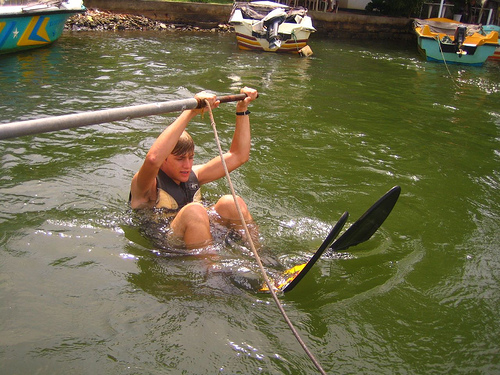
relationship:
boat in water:
[2, 2, 88, 55] [5, 30, 498, 374]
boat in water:
[411, 14, 499, 62] [5, 30, 498, 374]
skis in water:
[231, 184, 403, 295] [5, 30, 498, 374]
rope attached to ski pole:
[204, 99, 326, 374] [0, 94, 262, 139]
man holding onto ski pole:
[128, 86, 262, 273] [0, 94, 262, 139]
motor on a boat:
[455, 25, 467, 56] [411, 14, 499, 62]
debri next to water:
[65, 7, 234, 33] [5, 30, 498, 374]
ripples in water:
[2, 39, 498, 372] [5, 30, 498, 374]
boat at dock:
[411, 14, 499, 62] [85, 0, 499, 47]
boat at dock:
[226, 0, 318, 59] [85, 0, 499, 47]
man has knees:
[128, 86, 262, 273] [184, 192, 243, 221]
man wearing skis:
[128, 86, 262, 273] [231, 184, 403, 295]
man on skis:
[128, 86, 262, 273] [231, 184, 403, 295]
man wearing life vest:
[128, 86, 262, 273] [128, 170, 202, 229]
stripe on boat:
[427, 56, 483, 67] [411, 14, 499, 62]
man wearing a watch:
[128, 86, 262, 273] [235, 109, 250, 116]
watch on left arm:
[235, 109, 250, 116] [197, 105, 251, 181]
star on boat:
[11, 28, 20, 37] [2, 2, 88, 55]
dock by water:
[85, 0, 499, 47] [5, 30, 498, 374]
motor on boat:
[262, 7, 288, 53] [226, 0, 318, 59]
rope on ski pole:
[204, 99, 326, 374] [0, 94, 262, 139]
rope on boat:
[437, 35, 460, 91] [411, 14, 499, 62]